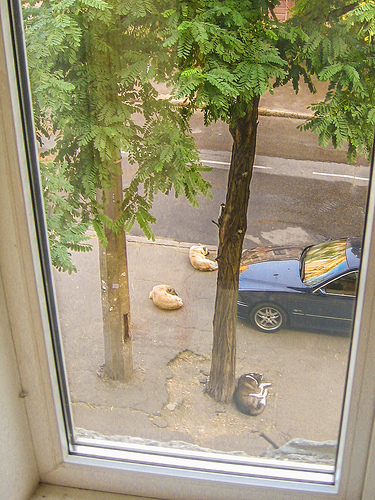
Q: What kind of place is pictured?
A: It is a sidewalk.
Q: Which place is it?
A: It is a sidewalk.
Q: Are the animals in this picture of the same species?
A: Yes, all the animals are dogs.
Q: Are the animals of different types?
A: No, all the animals are dogs.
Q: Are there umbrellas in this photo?
A: No, there are no umbrellas.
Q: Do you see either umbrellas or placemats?
A: No, there are no umbrellas or placemats.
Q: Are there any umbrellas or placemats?
A: No, there are no umbrellas or placemats.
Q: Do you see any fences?
A: No, there are no fences.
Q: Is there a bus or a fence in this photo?
A: No, there are no fences or buses.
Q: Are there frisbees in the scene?
A: No, there are no frisbees.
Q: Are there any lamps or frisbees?
A: No, there are no frisbees or lamps.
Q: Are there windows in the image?
A: Yes, there is a window.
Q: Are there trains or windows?
A: Yes, there is a window.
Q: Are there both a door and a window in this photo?
A: No, there is a window but no doors.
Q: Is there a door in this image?
A: No, there are no doors.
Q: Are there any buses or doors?
A: No, there are no doors or buses.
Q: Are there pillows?
A: No, there are no pillows.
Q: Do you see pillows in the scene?
A: No, there are no pillows.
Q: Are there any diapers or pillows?
A: No, there are no pillows or diapers.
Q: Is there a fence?
A: No, there are no fences.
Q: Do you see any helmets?
A: No, there are no helmets.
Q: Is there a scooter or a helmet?
A: No, there are no helmets or scooters.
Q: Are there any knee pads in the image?
A: No, there are no knee pads.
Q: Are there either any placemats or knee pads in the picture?
A: No, there are no knee pads or placemats.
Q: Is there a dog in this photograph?
A: Yes, there is a dog.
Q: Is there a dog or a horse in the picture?
A: Yes, there is a dog.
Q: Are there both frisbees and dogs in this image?
A: No, there is a dog but no frisbees.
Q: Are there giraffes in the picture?
A: No, there are no giraffes.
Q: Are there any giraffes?
A: No, there are no giraffes.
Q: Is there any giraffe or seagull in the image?
A: No, there are no giraffes or seagulls.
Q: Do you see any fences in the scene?
A: No, there are no fences.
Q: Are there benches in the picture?
A: No, there are no benches.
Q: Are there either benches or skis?
A: No, there are no benches or skis.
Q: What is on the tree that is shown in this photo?
A: The leaves are on the tree.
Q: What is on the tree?
A: The leaves are on the tree.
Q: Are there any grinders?
A: No, there are no grinders.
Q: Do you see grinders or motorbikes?
A: No, there are no grinders or motorbikes.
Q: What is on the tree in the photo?
A: The leaves are on the tree.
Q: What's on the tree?
A: The leaves are on the tree.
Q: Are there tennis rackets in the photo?
A: No, there are no tennis rackets.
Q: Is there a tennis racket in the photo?
A: No, there are no rackets.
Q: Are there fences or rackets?
A: No, there are no rackets or fences.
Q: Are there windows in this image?
A: Yes, there is a window.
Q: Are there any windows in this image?
A: Yes, there is a window.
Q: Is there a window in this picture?
A: Yes, there is a window.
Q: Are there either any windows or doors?
A: Yes, there is a window.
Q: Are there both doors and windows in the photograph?
A: No, there is a window but no doors.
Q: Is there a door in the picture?
A: No, there are no doors.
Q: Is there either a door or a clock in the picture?
A: No, there are no doors or clocks.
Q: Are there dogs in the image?
A: Yes, there is a dog.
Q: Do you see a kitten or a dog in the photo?
A: Yes, there is a dog.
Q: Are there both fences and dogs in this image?
A: No, there is a dog but no fences.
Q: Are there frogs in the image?
A: No, there are no frogs.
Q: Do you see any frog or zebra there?
A: No, there are no frogs or zebras.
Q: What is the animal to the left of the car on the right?
A: The animal is a dog.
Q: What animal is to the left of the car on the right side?
A: The animal is a dog.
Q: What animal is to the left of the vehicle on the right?
A: The animal is a dog.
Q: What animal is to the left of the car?
A: The animal is a dog.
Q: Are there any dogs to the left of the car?
A: Yes, there is a dog to the left of the car.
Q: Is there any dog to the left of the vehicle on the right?
A: Yes, there is a dog to the left of the car.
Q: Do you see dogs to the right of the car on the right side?
A: No, the dog is to the left of the car.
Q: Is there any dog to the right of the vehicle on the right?
A: No, the dog is to the left of the car.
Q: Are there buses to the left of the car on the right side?
A: No, there is a dog to the left of the car.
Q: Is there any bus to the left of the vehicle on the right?
A: No, there is a dog to the left of the car.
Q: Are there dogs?
A: Yes, there is a dog.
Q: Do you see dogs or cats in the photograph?
A: Yes, there is a dog.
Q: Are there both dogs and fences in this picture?
A: No, there is a dog but no fences.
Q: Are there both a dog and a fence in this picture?
A: No, there is a dog but no fences.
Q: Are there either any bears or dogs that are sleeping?
A: Yes, the dog is sleeping.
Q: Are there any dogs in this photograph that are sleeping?
A: Yes, there is a dog that is sleeping.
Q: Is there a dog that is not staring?
A: Yes, there is a dog that is sleeping.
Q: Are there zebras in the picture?
A: No, there are no zebras.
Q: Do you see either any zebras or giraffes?
A: No, there are no zebras or giraffes.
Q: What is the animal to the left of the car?
A: The animal is a dog.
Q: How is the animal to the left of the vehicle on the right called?
A: The animal is a dog.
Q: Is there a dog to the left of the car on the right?
A: Yes, there is a dog to the left of the car.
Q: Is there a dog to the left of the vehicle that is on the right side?
A: Yes, there is a dog to the left of the car.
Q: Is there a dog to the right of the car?
A: No, the dog is to the left of the car.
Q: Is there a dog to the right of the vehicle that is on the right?
A: No, the dog is to the left of the car.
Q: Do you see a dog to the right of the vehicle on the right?
A: No, the dog is to the left of the car.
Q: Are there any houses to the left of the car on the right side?
A: No, there is a dog to the left of the car.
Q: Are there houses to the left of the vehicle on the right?
A: No, there is a dog to the left of the car.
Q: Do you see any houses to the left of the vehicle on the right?
A: No, there is a dog to the left of the car.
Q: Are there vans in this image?
A: No, there are no vans.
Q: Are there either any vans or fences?
A: No, there are no vans or fences.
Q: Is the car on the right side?
A: Yes, the car is on the right of the image.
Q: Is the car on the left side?
A: No, the car is on the right of the image.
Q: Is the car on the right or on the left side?
A: The car is on the right of the image.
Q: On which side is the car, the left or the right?
A: The car is on the right of the image.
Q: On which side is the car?
A: The car is on the right of the image.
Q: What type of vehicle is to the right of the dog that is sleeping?
A: The vehicle is a car.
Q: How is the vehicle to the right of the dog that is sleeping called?
A: The vehicle is a car.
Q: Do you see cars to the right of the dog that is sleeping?
A: Yes, there is a car to the right of the dog.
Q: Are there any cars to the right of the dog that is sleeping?
A: Yes, there is a car to the right of the dog.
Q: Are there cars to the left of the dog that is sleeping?
A: No, the car is to the right of the dog.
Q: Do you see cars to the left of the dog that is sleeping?
A: No, the car is to the right of the dog.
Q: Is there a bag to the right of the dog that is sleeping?
A: No, there is a car to the right of the dog.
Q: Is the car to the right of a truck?
A: No, the car is to the right of a dog.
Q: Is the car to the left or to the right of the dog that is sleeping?
A: The car is to the right of the dog.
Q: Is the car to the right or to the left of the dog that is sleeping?
A: The car is to the right of the dog.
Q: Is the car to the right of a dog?
A: Yes, the car is to the right of a dog.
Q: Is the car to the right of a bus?
A: No, the car is to the right of a dog.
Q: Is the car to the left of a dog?
A: No, the car is to the right of a dog.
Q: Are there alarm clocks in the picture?
A: No, there are no alarm clocks.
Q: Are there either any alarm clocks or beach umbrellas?
A: No, there are no alarm clocks or beach umbrellas.